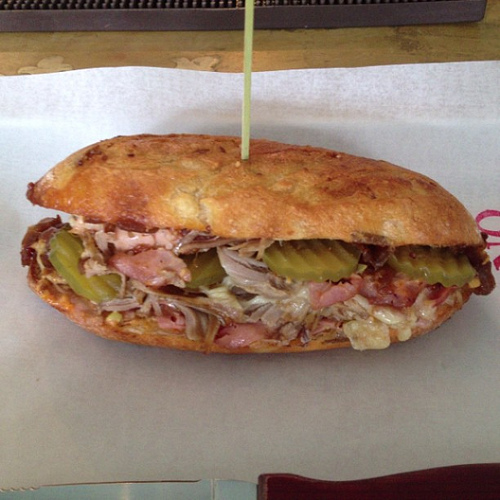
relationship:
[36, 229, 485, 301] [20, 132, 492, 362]
pickles in sandwich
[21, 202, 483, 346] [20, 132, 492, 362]
meat in sandwich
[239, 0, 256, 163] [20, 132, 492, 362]
stick sticking out of sandwich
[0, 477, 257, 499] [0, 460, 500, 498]
blade on knife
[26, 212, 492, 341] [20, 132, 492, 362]
meaty filling in sandwich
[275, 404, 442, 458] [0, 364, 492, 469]
section of countertop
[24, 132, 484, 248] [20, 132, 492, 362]
toasted bun on sandwich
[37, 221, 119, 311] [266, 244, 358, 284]
pickle in sandwich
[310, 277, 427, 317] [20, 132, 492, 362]
pulled pork in sandwich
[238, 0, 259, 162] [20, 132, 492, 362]
green pick in sandwich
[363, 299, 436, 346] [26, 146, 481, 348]
cheese in sandwich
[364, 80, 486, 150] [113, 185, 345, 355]
sheet holds sub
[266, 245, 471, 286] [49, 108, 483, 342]
pickles in sub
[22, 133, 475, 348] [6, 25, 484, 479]
sub on table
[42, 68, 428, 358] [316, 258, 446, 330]
sandwich with pork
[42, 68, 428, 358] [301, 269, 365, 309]
sandwich with ham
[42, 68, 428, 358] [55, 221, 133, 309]
sandwich with pickles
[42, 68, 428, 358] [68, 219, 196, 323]
sandwich with cheese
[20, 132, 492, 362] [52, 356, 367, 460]
sandwich on white paper